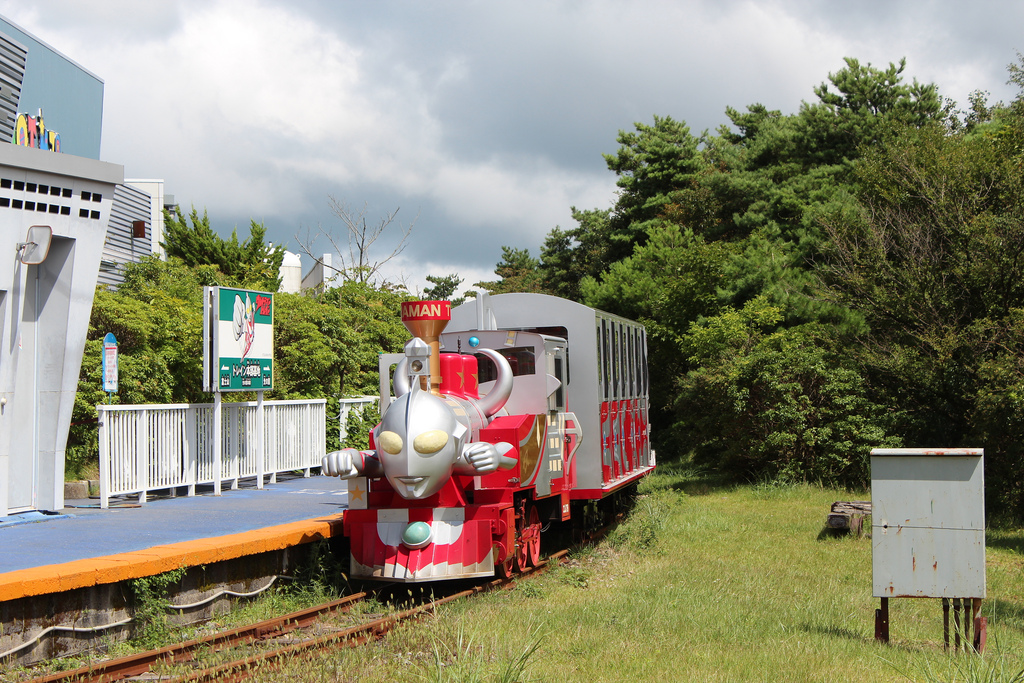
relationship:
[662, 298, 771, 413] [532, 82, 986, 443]
leaves on tree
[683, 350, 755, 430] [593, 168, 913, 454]
leaves on tree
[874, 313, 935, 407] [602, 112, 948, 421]
leaves on tree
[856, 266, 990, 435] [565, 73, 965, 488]
leaves on tree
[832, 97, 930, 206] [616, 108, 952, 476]
leaves on tree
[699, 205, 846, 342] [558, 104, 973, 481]
leaves on tree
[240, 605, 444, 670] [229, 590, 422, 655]
weeds by train tracks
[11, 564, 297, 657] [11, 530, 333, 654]
cable hanging on foundation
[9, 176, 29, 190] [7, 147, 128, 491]
window on building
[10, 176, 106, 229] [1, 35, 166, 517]
window on building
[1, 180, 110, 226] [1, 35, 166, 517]
windows on building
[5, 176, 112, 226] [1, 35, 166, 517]
window on building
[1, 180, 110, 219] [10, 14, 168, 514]
window on building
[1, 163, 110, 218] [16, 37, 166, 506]
window on building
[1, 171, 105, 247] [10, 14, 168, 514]
window on building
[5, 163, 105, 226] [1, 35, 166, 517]
window on building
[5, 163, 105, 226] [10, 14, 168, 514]
window on building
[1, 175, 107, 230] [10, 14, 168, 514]
window on building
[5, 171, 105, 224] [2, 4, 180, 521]
window on building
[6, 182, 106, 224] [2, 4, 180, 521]
window on building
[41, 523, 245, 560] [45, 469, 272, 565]
line painted platform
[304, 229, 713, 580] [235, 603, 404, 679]
train on tracks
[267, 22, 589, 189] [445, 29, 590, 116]
cloud coved sky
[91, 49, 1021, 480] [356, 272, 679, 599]
trees behind train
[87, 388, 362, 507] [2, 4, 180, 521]
wall side building